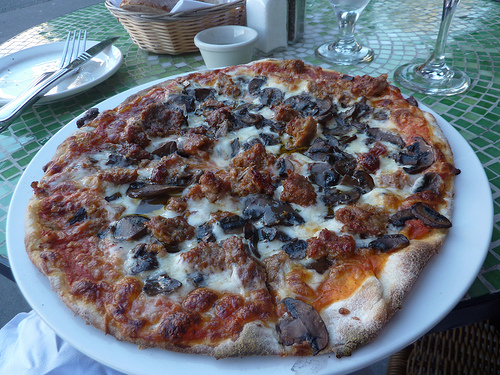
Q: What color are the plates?
A: White.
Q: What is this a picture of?
A: Pizza.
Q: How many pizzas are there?
A: 1.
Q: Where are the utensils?
A: Small plate.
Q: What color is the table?
A: Green.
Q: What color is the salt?
A: White.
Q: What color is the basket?
A: Brown.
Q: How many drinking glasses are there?
A: 2.